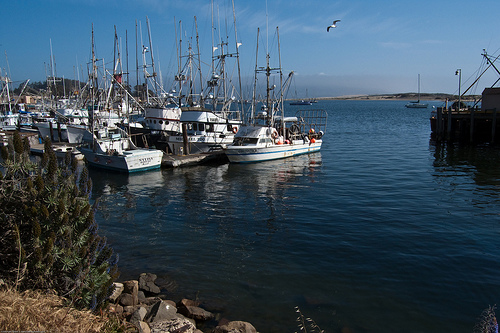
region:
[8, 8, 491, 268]
boats in a harbor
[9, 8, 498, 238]
boats on a dock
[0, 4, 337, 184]
there are a lot of boats parked near the shore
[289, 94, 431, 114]
these boats are out on the water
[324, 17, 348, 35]
a bird flying in the air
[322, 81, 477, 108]
a strip of land in the background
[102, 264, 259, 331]
rocks near the shoreline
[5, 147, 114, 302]
rough vegetation growin on the shore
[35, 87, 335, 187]
these boats are white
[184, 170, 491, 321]
the water is calm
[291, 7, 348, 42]
a bird is in the air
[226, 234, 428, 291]
the water is calm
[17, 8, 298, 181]
boats anchored on the shore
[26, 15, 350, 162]
the boats are white in colour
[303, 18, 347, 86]
the sky has clouds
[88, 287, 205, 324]
rocks are on the side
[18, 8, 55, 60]
the sky is blue in colour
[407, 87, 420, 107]
boats are in the water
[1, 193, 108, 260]
the bush is on the side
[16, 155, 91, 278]
the flowers are dark in colour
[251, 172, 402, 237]
tranquil blue water in the bay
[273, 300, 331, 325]
edge of white flower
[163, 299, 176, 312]
tiny white line on small rock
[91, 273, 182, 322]
cluster of rocks on the shore line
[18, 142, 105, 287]
evergreen bushes on shore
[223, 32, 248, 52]
tiny white flag on pole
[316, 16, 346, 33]
white seagull flying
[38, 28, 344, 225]
white boats in the harbor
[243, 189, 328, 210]
tiny ripples on top of water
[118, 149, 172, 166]
name at back of boat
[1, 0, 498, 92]
a bright blue sky with few clouds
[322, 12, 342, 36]
one sea gull flying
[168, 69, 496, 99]
hazy mountains in the distance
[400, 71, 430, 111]
a sailboat floating in the open water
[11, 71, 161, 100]
trees behind the boats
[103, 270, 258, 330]
brown rocks by the shore line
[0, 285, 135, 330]
tufts of brown grass by the rocks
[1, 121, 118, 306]
an evergreen bush by the water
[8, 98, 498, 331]
a large body of rippling blue water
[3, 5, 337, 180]
a group of boats parked at a dock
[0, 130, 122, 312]
evergreen shrub next to the water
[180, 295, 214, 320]
gray rock in the water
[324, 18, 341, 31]
bird flying over the water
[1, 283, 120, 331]
dry grass in front of the shrub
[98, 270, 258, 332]
rock pile to the right of shrub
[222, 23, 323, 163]
boat in the water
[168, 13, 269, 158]
boat next to boat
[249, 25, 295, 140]
tall mast on boat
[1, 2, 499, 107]
sky above water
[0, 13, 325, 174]
boats floating in water